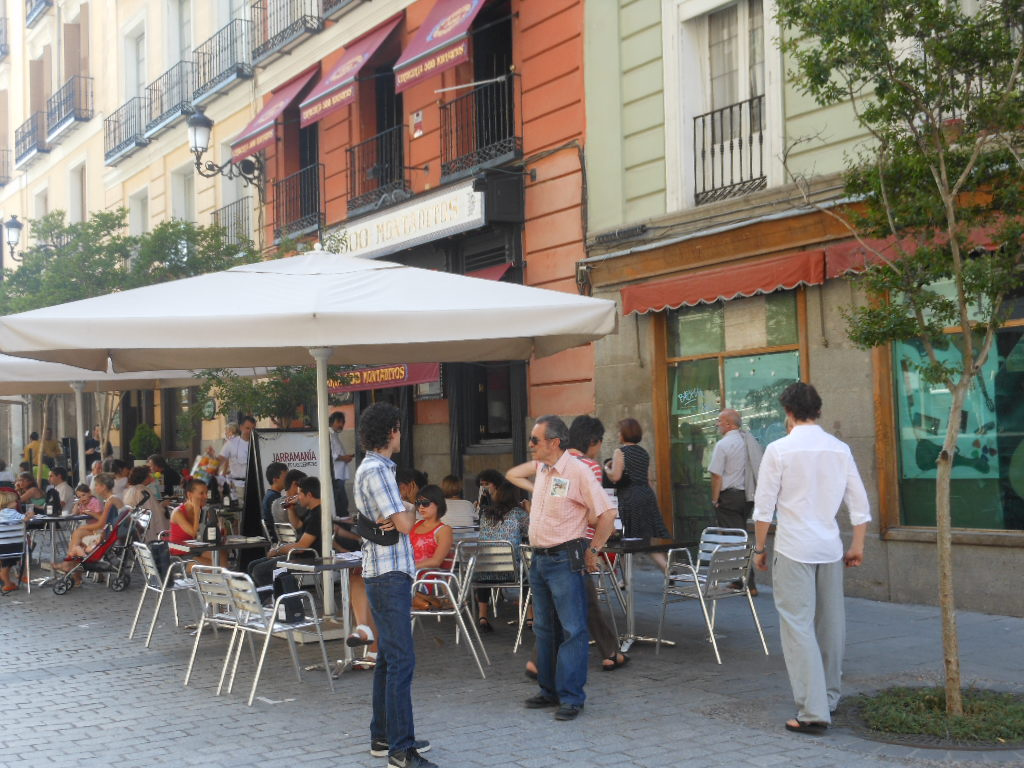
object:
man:
[525, 415, 616, 722]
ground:
[0, 572, 1021, 768]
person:
[704, 408, 764, 599]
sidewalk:
[0, 531, 1024, 768]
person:
[600, 417, 674, 591]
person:
[213, 416, 256, 511]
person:
[167, 479, 228, 574]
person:
[471, 481, 534, 631]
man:
[350, 405, 441, 767]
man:
[751, 380, 871, 734]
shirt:
[353, 451, 416, 580]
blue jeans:
[362, 571, 414, 759]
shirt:
[528, 448, 616, 548]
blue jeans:
[528, 538, 589, 703]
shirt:
[751, 424, 872, 563]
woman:
[345, 483, 454, 674]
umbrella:
[0, 242, 618, 648]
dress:
[410, 520, 449, 594]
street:
[0, 529, 1024, 768]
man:
[246, 477, 322, 603]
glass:
[280, 495, 299, 512]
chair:
[655, 527, 768, 666]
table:
[599, 534, 698, 653]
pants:
[770, 551, 846, 724]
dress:
[616, 444, 673, 540]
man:
[707, 409, 762, 598]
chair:
[216, 571, 336, 707]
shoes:
[526, 690, 584, 722]